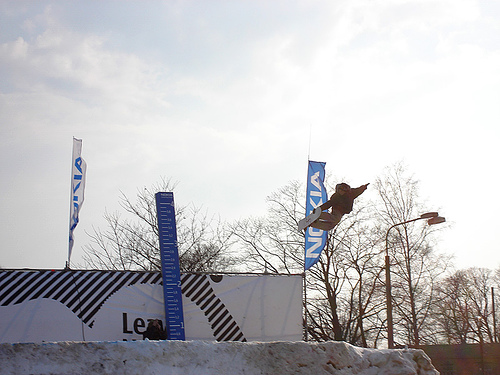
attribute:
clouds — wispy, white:
[24, 23, 477, 158]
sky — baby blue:
[3, 1, 493, 285]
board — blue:
[141, 183, 201, 345]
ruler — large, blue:
[154, 189, 183, 337]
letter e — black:
[132, 315, 147, 335]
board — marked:
[273, 208, 316, 235]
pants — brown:
[280, 210, 372, 250]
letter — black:
[121, 310, 134, 333]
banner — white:
[64, 135, 90, 274]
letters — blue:
[73, 152, 87, 230]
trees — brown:
[97, 165, 498, 340]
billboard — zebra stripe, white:
[2, 264, 306, 343]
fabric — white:
[63, 136, 88, 267]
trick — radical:
[297, 181, 371, 231]